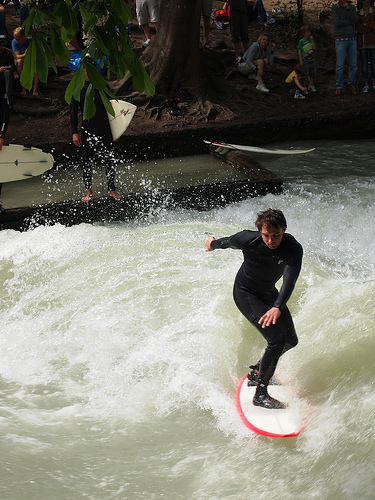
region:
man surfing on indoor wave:
[193, 189, 357, 452]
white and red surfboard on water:
[241, 324, 309, 456]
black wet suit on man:
[242, 233, 298, 392]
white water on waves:
[76, 353, 215, 426]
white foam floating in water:
[51, 460, 106, 498]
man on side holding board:
[79, 33, 140, 208]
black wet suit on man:
[71, 85, 125, 189]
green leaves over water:
[33, 3, 157, 91]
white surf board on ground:
[213, 126, 308, 163]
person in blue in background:
[10, 21, 47, 92]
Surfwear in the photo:
[196, 207, 317, 388]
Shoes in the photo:
[241, 359, 298, 410]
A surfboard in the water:
[230, 362, 308, 442]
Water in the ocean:
[112, 418, 238, 489]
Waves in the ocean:
[95, 253, 209, 349]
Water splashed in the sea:
[92, 263, 199, 358]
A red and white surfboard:
[215, 361, 313, 445]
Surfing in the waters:
[183, 204, 332, 419]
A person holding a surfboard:
[50, 61, 181, 205]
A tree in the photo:
[67, 5, 207, 101]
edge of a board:
[234, 411, 281, 457]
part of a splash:
[188, 349, 205, 380]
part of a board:
[262, 410, 293, 450]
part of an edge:
[243, 415, 260, 453]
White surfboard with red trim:
[237, 369, 309, 438]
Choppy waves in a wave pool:
[1, 177, 373, 497]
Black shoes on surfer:
[246, 363, 288, 410]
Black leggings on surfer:
[233, 283, 300, 383]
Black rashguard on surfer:
[210, 230, 303, 311]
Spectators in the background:
[0, 0, 372, 205]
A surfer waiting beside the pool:
[69, 54, 137, 203]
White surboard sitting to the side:
[201, 138, 314, 156]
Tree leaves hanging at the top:
[1, 0, 155, 121]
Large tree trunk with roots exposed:
[109, 0, 241, 121]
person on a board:
[203, 194, 318, 451]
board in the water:
[232, 365, 308, 445]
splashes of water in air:
[70, 163, 174, 215]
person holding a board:
[62, 46, 133, 199]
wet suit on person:
[64, 81, 124, 182]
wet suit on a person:
[228, 230, 296, 376]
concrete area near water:
[104, 150, 365, 178]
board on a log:
[203, 134, 320, 162]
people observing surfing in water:
[216, 10, 369, 96]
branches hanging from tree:
[3, 6, 170, 123]